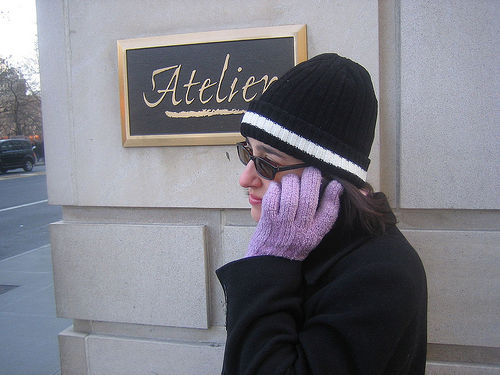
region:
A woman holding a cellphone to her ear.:
[213, 35, 438, 372]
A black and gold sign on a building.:
[107, 20, 318, 145]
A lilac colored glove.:
[246, 165, 341, 260]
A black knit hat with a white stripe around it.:
[237, 47, 387, 184]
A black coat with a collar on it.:
[185, 190, 432, 370]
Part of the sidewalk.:
[0, 240, 70, 370]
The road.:
[0, 161, 60, 256]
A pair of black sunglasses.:
[231, 140, 306, 185]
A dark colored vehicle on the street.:
[3, 137, 39, 172]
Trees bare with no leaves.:
[3, 48, 43, 139]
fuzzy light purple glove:
[235, 159, 342, 276]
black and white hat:
[230, 37, 381, 194]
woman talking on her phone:
[161, 38, 449, 372]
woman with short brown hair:
[224, 58, 406, 236]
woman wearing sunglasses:
[222, 64, 379, 230]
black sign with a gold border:
[121, 35, 306, 143]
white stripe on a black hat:
[249, 99, 371, 190]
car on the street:
[3, 126, 39, 175]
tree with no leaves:
[0, 45, 55, 158]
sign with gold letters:
[128, 56, 300, 128]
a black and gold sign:
[116, 26, 314, 147]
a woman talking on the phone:
[221, 50, 428, 373]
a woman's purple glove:
[254, 170, 341, 262]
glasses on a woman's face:
[232, 138, 309, 174]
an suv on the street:
[1, 138, 36, 176]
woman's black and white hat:
[240, 52, 376, 186]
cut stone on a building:
[43, 201, 220, 229]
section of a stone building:
[36, 1, 497, 372]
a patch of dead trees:
[0, 58, 40, 133]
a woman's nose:
[240, 161, 262, 187]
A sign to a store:
[107, 21, 322, 150]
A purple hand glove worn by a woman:
[253, 165, 345, 265]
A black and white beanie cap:
[233, 36, 375, 182]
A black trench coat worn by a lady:
[197, 196, 449, 373]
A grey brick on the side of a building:
[32, 215, 219, 332]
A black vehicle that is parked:
[0, 131, 38, 176]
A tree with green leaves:
[0, 52, 40, 136]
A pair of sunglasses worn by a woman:
[218, 132, 313, 181]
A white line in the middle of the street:
[0, 197, 49, 212]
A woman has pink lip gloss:
[230, 188, 265, 210]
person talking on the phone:
[174, 55, 421, 351]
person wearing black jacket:
[199, 188, 481, 347]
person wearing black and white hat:
[193, 61, 410, 193]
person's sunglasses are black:
[218, 130, 330, 195]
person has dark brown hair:
[282, 114, 393, 249]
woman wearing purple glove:
[218, 158, 334, 300]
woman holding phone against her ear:
[202, 86, 373, 306]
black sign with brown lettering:
[93, 67, 381, 185]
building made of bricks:
[35, 121, 315, 372]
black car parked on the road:
[3, 125, 51, 222]